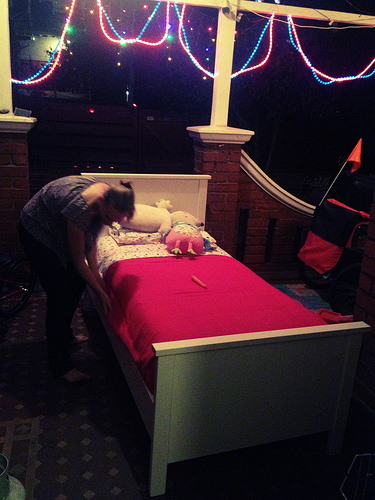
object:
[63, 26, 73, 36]
light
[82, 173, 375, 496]
bed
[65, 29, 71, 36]
light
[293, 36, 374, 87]
light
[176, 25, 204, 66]
light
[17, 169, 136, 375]
woman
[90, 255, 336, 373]
comforter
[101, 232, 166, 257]
sheet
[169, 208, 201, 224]
ponytail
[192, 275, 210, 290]
carrot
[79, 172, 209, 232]
headboard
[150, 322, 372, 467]
footboard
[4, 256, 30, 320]
bicycle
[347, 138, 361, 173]
flag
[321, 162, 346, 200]
pole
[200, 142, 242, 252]
column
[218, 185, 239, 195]
brick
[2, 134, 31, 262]
column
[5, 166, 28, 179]
brick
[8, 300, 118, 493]
carpet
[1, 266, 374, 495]
floor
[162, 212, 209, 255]
toy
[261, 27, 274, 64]
light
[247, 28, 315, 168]
tree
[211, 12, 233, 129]
post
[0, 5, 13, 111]
post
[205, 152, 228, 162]
brick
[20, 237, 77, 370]
pants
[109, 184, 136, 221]
hair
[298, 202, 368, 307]
wheel chair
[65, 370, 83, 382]
foot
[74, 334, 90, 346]
foot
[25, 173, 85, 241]
shirt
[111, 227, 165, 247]
pillow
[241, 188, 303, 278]
wall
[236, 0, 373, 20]
beam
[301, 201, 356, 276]
blanket